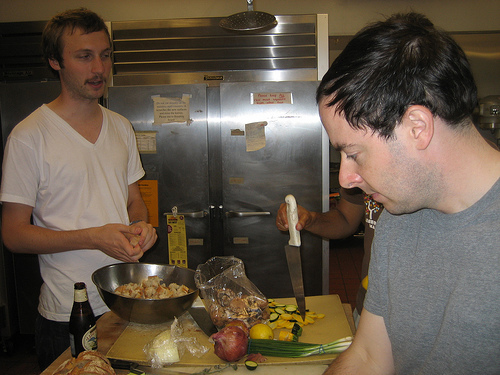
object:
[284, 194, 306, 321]
knife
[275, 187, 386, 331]
guy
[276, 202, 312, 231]
hand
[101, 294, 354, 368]
chopping board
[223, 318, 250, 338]
red onions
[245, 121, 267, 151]
note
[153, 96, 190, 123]
note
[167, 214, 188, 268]
note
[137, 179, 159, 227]
note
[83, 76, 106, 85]
mustache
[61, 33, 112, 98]
man's face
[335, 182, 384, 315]
shirt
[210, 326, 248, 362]
red onion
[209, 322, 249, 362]
onion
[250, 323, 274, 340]
lemon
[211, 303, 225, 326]
item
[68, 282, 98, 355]
bottle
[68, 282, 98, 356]
beer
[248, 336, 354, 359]
bunch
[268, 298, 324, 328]
sliced vegetables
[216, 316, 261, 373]
onions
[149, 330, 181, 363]
onion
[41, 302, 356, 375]
counter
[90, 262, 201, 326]
bowl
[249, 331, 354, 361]
onions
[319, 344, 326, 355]
rubber band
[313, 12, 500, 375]
guys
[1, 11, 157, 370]
guys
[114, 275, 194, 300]
food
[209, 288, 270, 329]
food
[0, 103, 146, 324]
shirt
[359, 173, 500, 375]
shirt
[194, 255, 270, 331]
bag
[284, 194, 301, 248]
handle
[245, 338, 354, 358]
green onions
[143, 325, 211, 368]
plastic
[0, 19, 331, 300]
refrigerater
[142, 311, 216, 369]
cellophane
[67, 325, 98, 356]
label